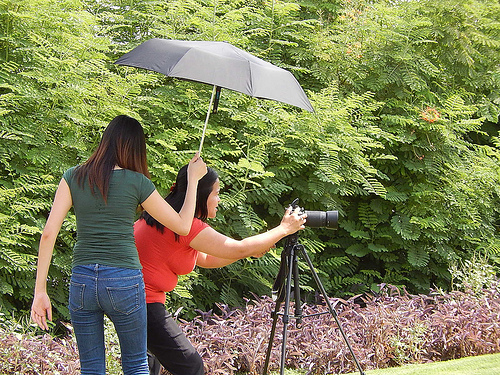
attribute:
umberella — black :
[118, 24, 323, 124]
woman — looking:
[176, 160, 249, 252]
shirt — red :
[43, 162, 155, 274]